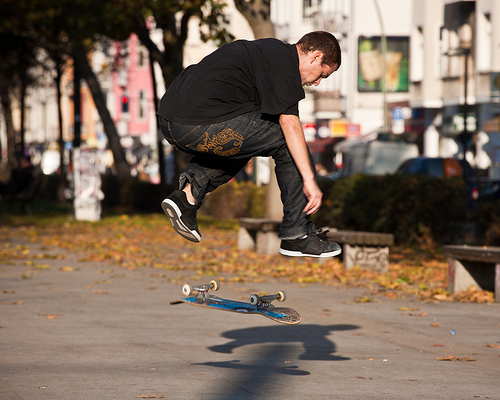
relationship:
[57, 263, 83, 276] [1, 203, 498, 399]
leaf on ground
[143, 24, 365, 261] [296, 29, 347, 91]
skateboarder has head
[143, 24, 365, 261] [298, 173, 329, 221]
skateboarder has hand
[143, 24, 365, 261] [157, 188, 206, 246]
skateboarder has foot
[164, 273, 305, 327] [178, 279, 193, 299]
skateboard has wheel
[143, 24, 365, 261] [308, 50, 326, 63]
skateboarder has ear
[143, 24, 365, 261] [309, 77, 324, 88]
skateboarder has nose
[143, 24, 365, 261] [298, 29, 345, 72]
skateboarder has hair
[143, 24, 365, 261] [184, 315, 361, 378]
skateboarder has shadow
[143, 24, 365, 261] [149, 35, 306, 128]
skateboarder has shirt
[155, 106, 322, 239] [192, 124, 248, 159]
jeans have design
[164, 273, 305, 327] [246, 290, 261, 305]
skateboard has wheel